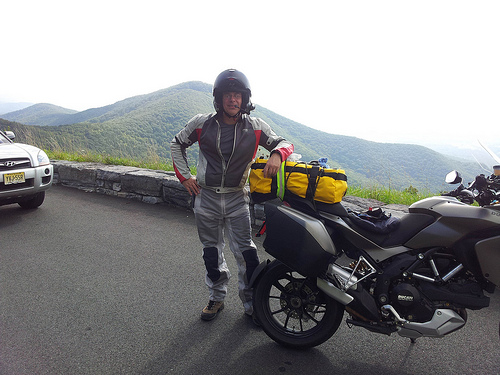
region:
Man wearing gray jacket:
[169, 64, 291, 331]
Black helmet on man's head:
[206, 62, 251, 114]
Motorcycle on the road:
[252, 178, 497, 350]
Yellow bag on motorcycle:
[247, 150, 347, 209]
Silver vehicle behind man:
[1, 126, 63, 218]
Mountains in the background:
[1, 81, 498, 216]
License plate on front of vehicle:
[1, 169, 29, 187]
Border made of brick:
[48, 150, 290, 236]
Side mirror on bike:
[432, 165, 472, 200]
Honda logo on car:
[5, 154, 17, 172]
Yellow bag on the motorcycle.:
[246, 151, 350, 201]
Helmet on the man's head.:
[211, 69, 256, 119]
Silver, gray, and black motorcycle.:
[252, 170, 495, 350]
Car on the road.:
[0, 125, 52, 214]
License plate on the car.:
[2, 169, 27, 186]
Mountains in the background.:
[1, 80, 491, 189]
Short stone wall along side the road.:
[50, 154, 210, 209]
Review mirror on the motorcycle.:
[442, 167, 463, 187]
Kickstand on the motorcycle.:
[404, 335, 421, 349]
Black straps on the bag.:
[251, 158, 346, 207]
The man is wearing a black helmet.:
[211, 67, 251, 117]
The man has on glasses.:
[213, 63, 245, 117]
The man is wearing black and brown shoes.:
[198, 297, 224, 319]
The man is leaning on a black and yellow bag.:
[247, 155, 347, 196]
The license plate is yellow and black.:
[3, 173, 29, 182]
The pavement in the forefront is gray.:
[31, 273, 130, 337]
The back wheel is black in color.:
[251, 261, 336, 350]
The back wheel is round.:
[250, 262, 341, 344]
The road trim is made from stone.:
[107, 170, 156, 191]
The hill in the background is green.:
[126, 118, 161, 148]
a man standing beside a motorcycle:
[168, 63, 498, 344]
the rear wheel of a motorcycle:
[243, 252, 344, 356]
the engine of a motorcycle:
[366, 253, 491, 342]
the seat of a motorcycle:
[323, 198, 428, 248]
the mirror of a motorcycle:
[442, 170, 464, 186]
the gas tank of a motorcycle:
[407, 193, 497, 244]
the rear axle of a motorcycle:
[286, 293, 306, 310]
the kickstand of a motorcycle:
[398, 335, 417, 372]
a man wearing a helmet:
[206, 67, 257, 123]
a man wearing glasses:
[205, 70, 263, 128]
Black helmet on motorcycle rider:
[200, 66, 260, 116]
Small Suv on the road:
[0, 111, 76, 211]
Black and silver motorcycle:
[235, 131, 497, 359]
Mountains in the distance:
[4, 75, 499, 222]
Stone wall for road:
[48, 152, 212, 214]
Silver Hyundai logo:
[1, 157, 19, 174]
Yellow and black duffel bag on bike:
[254, 145, 350, 213]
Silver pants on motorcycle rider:
[189, 176, 267, 318]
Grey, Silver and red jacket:
[157, 88, 300, 208]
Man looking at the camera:
[205, 68, 261, 133]